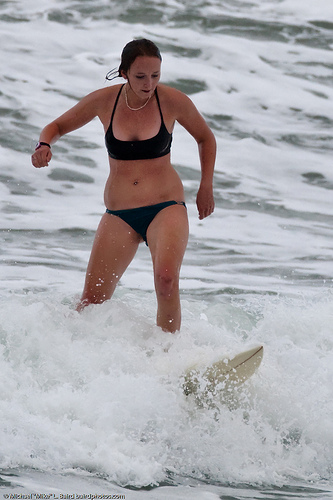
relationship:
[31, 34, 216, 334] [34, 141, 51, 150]
woman wearing black watch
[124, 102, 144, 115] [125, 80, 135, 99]
necklace on neck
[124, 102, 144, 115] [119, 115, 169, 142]
necklace on chest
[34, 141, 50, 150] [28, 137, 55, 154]
black watch on wrist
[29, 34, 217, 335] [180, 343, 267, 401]
woman surfing on board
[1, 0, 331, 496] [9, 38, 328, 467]
water in water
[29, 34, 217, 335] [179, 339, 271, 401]
woman on surfboard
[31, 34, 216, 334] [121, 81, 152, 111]
woman wearing necklace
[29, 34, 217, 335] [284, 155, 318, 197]
woman surfing in water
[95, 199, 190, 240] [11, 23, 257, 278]
bikini on woman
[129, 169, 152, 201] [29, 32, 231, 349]
belly button of woman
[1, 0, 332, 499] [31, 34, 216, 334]
water splashing around woman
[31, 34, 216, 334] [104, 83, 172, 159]
woman wearing black top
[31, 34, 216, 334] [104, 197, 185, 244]
woman wearing black bottom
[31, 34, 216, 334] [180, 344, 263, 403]
woman riding board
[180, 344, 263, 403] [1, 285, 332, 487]
board on wave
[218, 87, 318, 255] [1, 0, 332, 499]
white foam on water